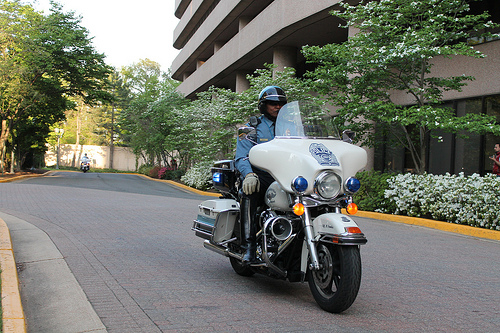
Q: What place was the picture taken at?
A: It was taken at the street.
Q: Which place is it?
A: It is a street.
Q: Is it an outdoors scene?
A: Yes, it is outdoors.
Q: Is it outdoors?
A: Yes, it is outdoors.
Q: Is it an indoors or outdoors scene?
A: It is outdoors.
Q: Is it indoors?
A: No, it is outdoors.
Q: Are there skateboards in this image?
A: No, there are no skateboards.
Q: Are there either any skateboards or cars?
A: No, there are no skateboards or cars.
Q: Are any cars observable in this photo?
A: No, there are no cars.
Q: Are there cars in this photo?
A: No, there are no cars.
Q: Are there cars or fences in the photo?
A: No, there are no cars or fences.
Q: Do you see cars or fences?
A: No, there are no cars or fences.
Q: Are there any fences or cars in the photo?
A: No, there are no cars or fences.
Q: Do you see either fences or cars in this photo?
A: No, there are no cars or fences.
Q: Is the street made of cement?
A: Yes, the street is made of cement.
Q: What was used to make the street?
A: The street is made of concrete.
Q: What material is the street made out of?
A: The street is made of concrete.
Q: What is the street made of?
A: The street is made of concrete.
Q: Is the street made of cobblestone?
A: No, the street is made of concrete.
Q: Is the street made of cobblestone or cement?
A: The street is made of cement.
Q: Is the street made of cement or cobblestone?
A: The street is made of cement.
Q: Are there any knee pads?
A: No, there are no knee pads.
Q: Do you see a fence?
A: No, there are no fences.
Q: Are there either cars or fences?
A: No, there are no fences or cars.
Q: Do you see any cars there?
A: No, there are no cars.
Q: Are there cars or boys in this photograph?
A: No, there are no cars or boys.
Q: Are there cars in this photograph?
A: No, there are no cars.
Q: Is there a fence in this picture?
A: No, there are no fences.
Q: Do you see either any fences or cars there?
A: No, there are no fences or cars.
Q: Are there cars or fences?
A: No, there are no fences or cars.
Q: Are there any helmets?
A: Yes, there is a helmet.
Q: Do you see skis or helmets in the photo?
A: Yes, there is a helmet.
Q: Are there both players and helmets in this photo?
A: No, there is a helmet but no players.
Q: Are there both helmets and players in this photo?
A: No, there is a helmet but no players.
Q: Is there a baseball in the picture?
A: No, there are no baseballs.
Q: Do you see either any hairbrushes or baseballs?
A: No, there are no baseballs or hairbrushes.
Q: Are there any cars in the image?
A: No, there are no cars.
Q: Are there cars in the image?
A: No, there are no cars.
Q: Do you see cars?
A: No, there are no cars.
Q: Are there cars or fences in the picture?
A: No, there are no cars or fences.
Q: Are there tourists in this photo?
A: No, there are no tourists.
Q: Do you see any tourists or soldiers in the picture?
A: No, there are no tourists or soldiers.